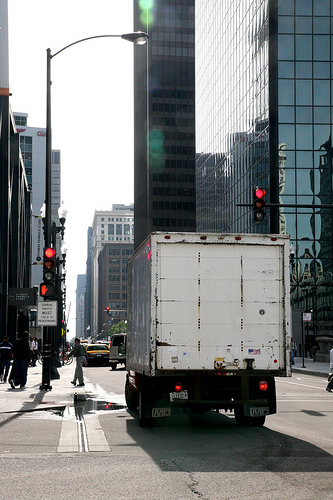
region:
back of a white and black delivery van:
[109, 223, 302, 441]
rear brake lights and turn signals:
[158, 367, 282, 416]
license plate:
[164, 387, 190, 406]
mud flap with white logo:
[137, 378, 175, 422]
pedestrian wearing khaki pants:
[65, 333, 88, 389]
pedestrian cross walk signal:
[34, 276, 61, 306]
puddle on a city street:
[41, 386, 125, 428]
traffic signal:
[40, 241, 58, 285]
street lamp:
[37, 16, 153, 247]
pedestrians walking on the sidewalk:
[0, 327, 39, 387]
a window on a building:
[107, 249, 113, 255]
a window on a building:
[116, 248, 121, 254]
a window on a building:
[110, 257, 117, 267]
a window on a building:
[120, 257, 125, 263]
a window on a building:
[112, 267, 118, 273]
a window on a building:
[120, 268, 126, 273]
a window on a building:
[115, 274, 120, 281]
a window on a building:
[110, 300, 117, 309]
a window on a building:
[111, 300, 114, 306]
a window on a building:
[112, 308, 118, 317]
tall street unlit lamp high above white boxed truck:
[118, 25, 150, 48]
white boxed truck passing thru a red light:
[121, 228, 292, 426]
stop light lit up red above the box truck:
[250, 180, 268, 227]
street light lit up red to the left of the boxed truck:
[39, 242, 61, 284]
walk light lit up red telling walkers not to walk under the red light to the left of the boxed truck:
[38, 281, 56, 297]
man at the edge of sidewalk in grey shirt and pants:
[62, 332, 92, 387]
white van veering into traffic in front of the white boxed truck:
[107, 328, 128, 370]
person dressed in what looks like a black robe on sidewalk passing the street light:
[8, 319, 34, 392]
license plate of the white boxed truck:
[168, 390, 194, 401]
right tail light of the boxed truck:
[254, 377, 270, 392]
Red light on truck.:
[156, 361, 186, 398]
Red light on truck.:
[256, 336, 284, 405]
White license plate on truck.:
[157, 384, 215, 419]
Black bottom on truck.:
[139, 384, 309, 431]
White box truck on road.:
[128, 304, 201, 378]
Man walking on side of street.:
[58, 330, 110, 444]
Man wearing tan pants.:
[72, 358, 118, 412]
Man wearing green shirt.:
[63, 333, 96, 384]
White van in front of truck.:
[98, 333, 157, 438]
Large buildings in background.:
[68, 278, 133, 398]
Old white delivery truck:
[119, 227, 303, 431]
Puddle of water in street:
[31, 379, 128, 431]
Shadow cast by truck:
[110, 382, 332, 483]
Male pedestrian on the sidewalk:
[66, 333, 95, 390]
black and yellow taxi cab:
[83, 337, 116, 371]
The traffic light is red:
[38, 243, 60, 281]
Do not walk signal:
[34, 280, 63, 301]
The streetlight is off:
[39, 29, 156, 56]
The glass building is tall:
[190, 4, 327, 362]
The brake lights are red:
[157, 375, 295, 401]